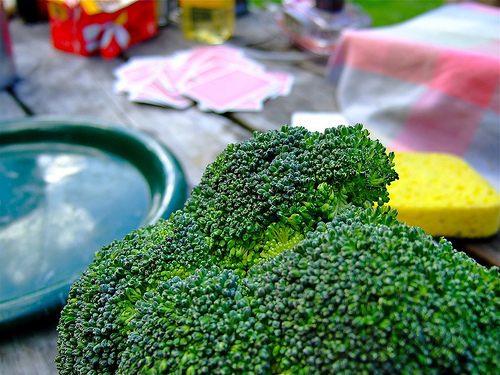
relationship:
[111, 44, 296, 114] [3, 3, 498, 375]
cards are on table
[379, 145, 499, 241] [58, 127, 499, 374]
sponge beside broccoli